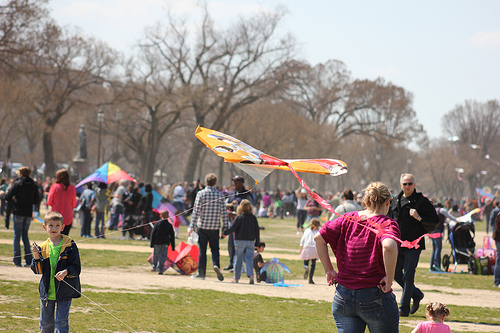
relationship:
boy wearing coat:
[32, 214, 84, 328] [27, 241, 87, 298]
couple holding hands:
[193, 177, 262, 281] [223, 223, 231, 241]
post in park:
[96, 112, 110, 172] [4, 150, 499, 328]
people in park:
[38, 169, 197, 226] [4, 150, 499, 328]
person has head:
[150, 175, 192, 269] [152, 206, 165, 216]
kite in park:
[199, 123, 344, 195] [4, 150, 499, 328]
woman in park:
[231, 197, 263, 281] [4, 150, 499, 328]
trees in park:
[17, 29, 393, 122] [4, 150, 499, 328]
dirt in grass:
[95, 243, 149, 251] [98, 248, 151, 265]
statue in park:
[78, 124, 89, 177] [4, 150, 499, 328]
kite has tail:
[199, 123, 344, 195] [291, 174, 336, 217]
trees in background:
[17, 29, 393, 122] [12, 17, 487, 195]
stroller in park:
[442, 198, 492, 268] [4, 150, 499, 328]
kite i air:
[199, 123, 344, 195] [151, 110, 393, 234]